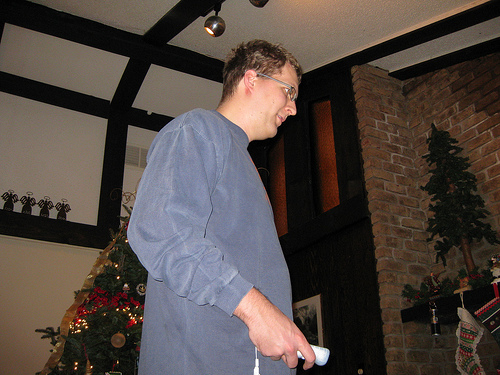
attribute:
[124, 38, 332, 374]
person — standing, playing wii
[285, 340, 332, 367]
remote control — plastic, white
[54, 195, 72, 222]
decoration — angel shaped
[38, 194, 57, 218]
decoration — small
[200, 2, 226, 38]
light — silver, on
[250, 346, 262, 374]
tassel — white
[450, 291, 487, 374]
stocking — hanging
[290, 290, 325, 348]
picture — white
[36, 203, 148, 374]
tree — decorated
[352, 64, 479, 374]
wall — brick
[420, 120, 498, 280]
tree — undecorated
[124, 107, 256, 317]
sleeve — long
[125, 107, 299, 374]
shirt — blue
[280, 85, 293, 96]
eye — open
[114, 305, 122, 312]
christmas light — on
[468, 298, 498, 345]
stocking — hanging